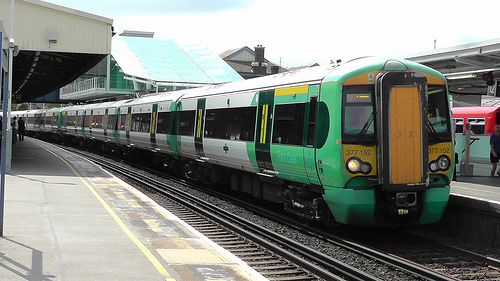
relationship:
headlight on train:
[344, 157, 363, 172] [66, 27, 443, 266]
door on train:
[255, 87, 275, 175] [13, 57, 455, 237]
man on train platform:
[490, 122, 499, 181] [444, 169, 499, 211]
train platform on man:
[0, 130, 275, 277] [490, 122, 499, 181]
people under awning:
[8, 113, 26, 139] [8, 0, 115, 102]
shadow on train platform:
[18, 245, 54, 277] [0, 134, 275, 280]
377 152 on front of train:
[340, 147, 373, 158] [111, 53, 438, 221]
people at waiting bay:
[15, 115, 27, 141] [13, 127, 50, 166]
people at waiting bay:
[15, 115, 27, 141] [8, 129, 86, 172]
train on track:
[120, 74, 468, 231] [62, 137, 498, 278]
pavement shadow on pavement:
[15, 129, 116, 181] [1, 129, 261, 279]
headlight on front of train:
[344, 155, 363, 177] [187, 30, 472, 245]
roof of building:
[112, 37, 245, 86] [58, 29, 245, 98]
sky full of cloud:
[54, 1, 498, 81] [105, 36, 149, 81]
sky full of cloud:
[54, 1, 498, 81] [115, 4, 497, 66]